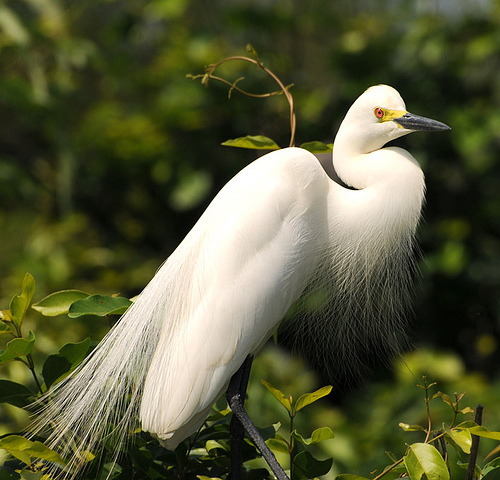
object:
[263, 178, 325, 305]
chest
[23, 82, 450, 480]
bird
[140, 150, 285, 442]
wing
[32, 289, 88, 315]
leaf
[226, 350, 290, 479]
legs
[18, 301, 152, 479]
tail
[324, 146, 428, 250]
neck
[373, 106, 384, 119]
eye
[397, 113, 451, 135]
beak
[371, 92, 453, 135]
face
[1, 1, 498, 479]
trees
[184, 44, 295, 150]
twig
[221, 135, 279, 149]
leaf